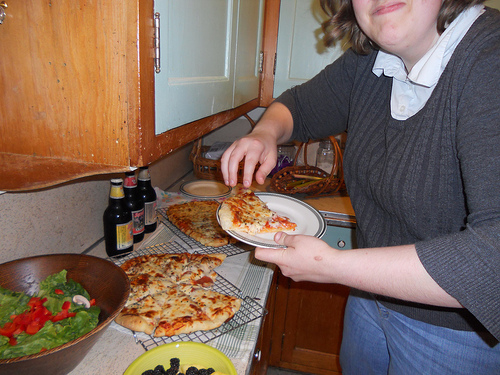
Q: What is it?
A: Pizza.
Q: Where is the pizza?
A: On the counter.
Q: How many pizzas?
A: 2.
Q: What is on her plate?
A: Pizza.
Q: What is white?
A: The plate.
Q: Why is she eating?
A: Hungry.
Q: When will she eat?
A: Soon.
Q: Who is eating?
A: The lady.